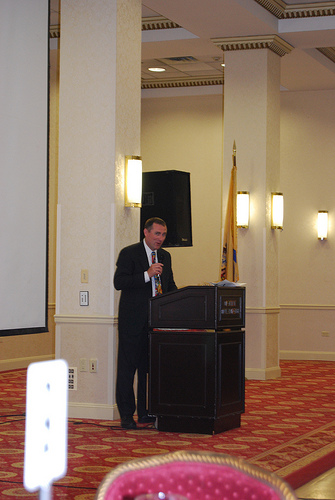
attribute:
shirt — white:
[136, 242, 168, 301]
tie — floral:
[141, 246, 168, 296]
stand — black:
[149, 282, 262, 445]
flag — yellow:
[217, 140, 248, 284]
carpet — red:
[256, 376, 327, 454]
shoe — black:
[111, 411, 162, 430]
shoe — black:
[135, 410, 158, 427]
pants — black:
[119, 324, 156, 436]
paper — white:
[211, 274, 253, 289]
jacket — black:
[113, 245, 178, 301]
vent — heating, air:
[160, 53, 200, 70]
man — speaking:
[109, 213, 179, 429]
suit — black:
[112, 243, 179, 430]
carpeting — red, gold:
[3, 360, 333, 498]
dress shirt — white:
[140, 240, 166, 295]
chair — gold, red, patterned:
[93, 445, 298, 497]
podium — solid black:
[145, 282, 249, 436]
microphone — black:
[152, 249, 172, 280]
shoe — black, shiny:
[118, 413, 138, 430]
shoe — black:
[138, 411, 149, 425]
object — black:
[140, 167, 193, 251]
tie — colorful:
[148, 251, 163, 296]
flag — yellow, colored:
[213, 137, 241, 285]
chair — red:
[75, 446, 298, 486]